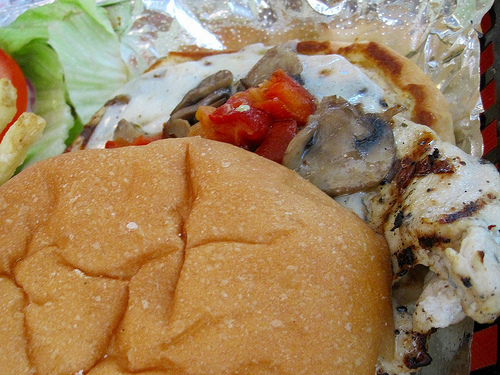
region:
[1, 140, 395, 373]
A golden brown bun.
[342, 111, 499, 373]
A seasoned piece of chicken.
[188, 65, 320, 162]
A small pile of tomatoes.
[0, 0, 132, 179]
A green piece of lettuce.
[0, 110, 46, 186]
A yellow french fry.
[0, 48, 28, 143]
A red slice of tomato.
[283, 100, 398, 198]
A slice of mushroom.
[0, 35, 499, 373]
A mushroom chicken sandwich.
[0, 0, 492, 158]
A foil food wrapper.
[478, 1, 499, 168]
A black plastic food basket.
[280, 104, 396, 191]
a mushroom on a plate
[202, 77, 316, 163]
peppers on a plate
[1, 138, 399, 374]
bun of a burger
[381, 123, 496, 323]
cheese that has melted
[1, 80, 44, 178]
ends of french fries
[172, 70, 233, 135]
mushrooms on a plate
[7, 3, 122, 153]
a few pieces of lettuce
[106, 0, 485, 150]
aluminum foil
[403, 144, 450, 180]
burnt bit of food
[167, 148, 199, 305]
crease on a bun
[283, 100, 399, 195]
A cooked plant mushroom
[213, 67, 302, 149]
A cooked red pepper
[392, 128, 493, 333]
A coked piece of meat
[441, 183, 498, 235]
Grill line in meat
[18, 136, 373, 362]
A brown hamburger bun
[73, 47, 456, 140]
A plain cheese pizza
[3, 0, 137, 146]
A leaf green lettuce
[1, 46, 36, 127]
Tomato and purple onion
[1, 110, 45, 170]
The tip of the french fry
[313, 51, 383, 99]
White cheese on pizza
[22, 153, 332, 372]
bun on the sandwich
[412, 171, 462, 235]
grilled chicken on the bun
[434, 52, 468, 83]
tinfoil under the sandwich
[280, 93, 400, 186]
mushroom on the bun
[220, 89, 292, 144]
tomatoes on the mushrooms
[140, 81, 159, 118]
egg whites on the bun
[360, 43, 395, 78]
grilled bun on the sandwich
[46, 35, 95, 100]
lettuce on the tinfoil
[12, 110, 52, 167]
french fry on the plate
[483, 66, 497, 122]
rack under the tinfoil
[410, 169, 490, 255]
grilled chicken on the bun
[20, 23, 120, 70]
lettuce on the tinfoil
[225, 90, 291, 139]
tomato on the mushrooms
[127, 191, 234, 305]
creases in the bun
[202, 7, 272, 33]
tinfoil under the bun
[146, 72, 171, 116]
egg white on the bun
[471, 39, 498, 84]
rack the tinfoil is on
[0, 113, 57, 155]
french fry beside the sandwich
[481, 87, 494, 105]
red underneath the rack